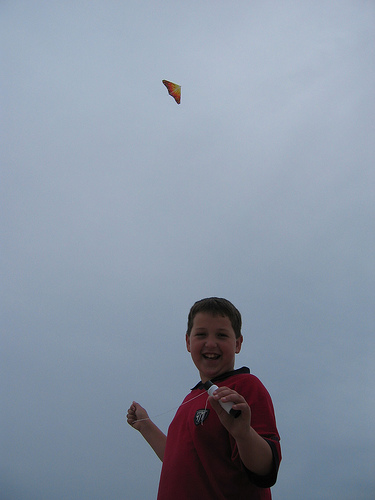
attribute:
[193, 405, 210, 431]
logo — black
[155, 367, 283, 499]
shirt — red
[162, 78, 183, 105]
kite — yellow, being handled, flying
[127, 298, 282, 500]
boy — smiling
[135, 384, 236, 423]
thread — white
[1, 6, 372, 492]
sky — clear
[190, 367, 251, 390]
collar — black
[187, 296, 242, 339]
hair — brown